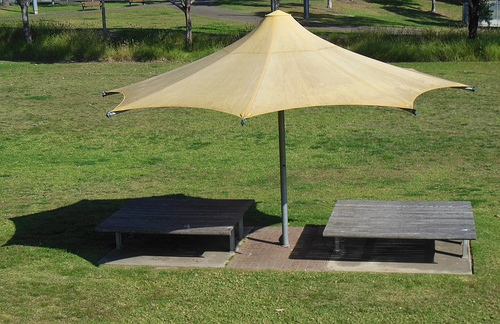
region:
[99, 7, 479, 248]
Tan shade umbrella on post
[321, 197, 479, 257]
Wooden platform on patio under umbrella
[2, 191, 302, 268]
Shadow of umbrella covering platform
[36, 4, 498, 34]
Paved road or pathway in park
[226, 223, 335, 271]
Brick rectangular patio beneath umbrella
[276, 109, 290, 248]
Gray metal pole supporting umbrella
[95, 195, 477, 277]
Two wooden platforms on brick and concrete patio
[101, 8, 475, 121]
the umbrella is yellow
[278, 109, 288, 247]
the pole is metal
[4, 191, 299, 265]
shadow of the umbrella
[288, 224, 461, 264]
shadow of the table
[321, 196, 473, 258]
table made of wood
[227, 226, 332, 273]
bricks on the ground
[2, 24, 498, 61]
a strip of tall grass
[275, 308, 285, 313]
leaf on the ground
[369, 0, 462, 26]
shadow of a tree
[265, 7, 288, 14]
top of the umbrella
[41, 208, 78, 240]
a shadow on the grass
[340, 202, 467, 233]
a table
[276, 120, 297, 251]
a grey pole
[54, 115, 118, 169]
the grass is short and green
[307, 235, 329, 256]
a shadow under the table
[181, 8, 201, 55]
a tree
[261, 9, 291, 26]
top of the umbrella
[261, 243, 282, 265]
bricks on the ground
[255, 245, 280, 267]
the ground is made of bricks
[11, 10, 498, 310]
this is at a park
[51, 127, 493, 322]
the field is made of grass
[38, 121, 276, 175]
the grass looks very healthy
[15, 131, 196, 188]
the grass is brown and green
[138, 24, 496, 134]
the umbrella is off white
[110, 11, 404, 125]
this umbrella is large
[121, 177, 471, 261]
the tables are wooden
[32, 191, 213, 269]
the table is shaded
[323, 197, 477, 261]
A table that is by a yellow umbrella.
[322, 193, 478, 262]
A table that is made of wood.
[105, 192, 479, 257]
Two tables that are made of wood.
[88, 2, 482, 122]
There is a yellow umbrella on a post.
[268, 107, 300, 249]
There is a metal post holding an umbrella.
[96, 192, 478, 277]
The tables are setting on concrete.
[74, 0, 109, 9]
A wood bench is in the background.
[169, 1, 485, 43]
The road is made of stone.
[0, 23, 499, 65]
The grass by the road is tall.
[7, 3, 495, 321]
a scene during the day time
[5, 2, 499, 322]
a scene outside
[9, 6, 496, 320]
an image at a park